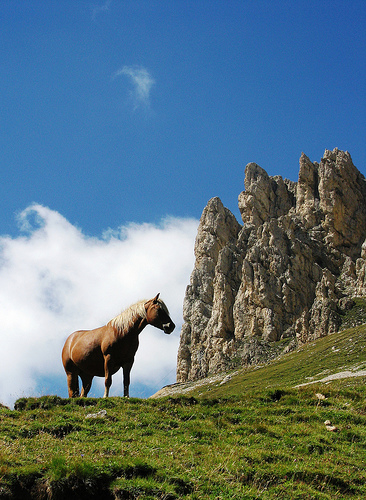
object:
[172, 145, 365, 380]
outcropping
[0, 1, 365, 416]
sky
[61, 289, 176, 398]
coat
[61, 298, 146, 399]
torso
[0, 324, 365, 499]
grass patch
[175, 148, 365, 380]
hill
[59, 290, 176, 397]
horse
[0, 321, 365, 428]
green grass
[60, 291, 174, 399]
blonde hair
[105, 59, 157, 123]
cloud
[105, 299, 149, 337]
blonde mane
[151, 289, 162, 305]
ear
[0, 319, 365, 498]
field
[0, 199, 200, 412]
cloud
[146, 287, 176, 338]
head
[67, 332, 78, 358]
light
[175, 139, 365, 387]
stone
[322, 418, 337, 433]
rock